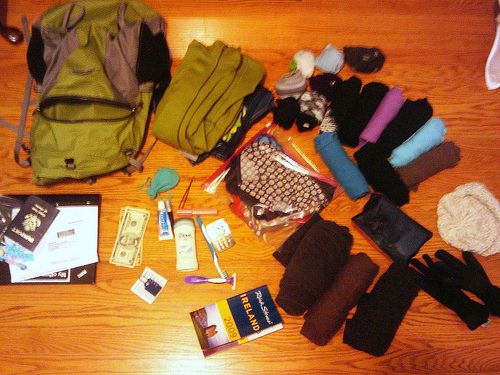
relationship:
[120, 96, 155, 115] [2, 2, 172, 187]
zipper on backpack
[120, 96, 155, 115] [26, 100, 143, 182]
zipper on compartment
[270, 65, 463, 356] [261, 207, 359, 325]
collection of shirt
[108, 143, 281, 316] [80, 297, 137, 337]
items on floor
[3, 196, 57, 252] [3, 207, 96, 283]
passport on paper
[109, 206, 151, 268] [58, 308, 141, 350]
money on floor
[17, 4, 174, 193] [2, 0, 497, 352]
backpack on floor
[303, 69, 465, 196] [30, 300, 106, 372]
clothes on floor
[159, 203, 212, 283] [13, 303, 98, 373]
deodorant on floor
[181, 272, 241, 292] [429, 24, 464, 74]
razor on floor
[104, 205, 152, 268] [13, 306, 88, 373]
money on table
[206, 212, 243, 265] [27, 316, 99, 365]
medication on table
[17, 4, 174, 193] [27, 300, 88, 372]
backpack on table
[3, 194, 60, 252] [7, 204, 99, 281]
passport on paper